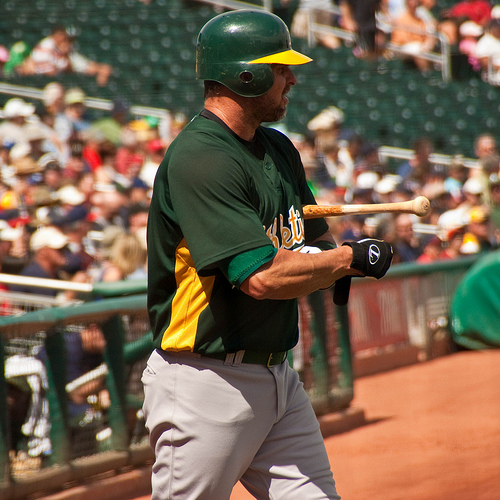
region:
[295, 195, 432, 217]
part of a brown bat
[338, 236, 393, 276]
a black and white glove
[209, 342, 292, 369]
a man's black belt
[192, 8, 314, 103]
a green and yellow helmet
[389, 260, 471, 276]
a long green pole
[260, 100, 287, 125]
a man's beard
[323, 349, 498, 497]
part of a tennis court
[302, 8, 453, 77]
a long gray rail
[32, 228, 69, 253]
a white baseball cap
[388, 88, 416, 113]
a green stadium seat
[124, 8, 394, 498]
Man wearing a green jersey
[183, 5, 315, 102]
Helmet on man's head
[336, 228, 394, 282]
Black glove on man's hand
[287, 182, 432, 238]
Bat under man's arm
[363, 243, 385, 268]
White logo on black glove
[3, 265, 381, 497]
Fence with green padding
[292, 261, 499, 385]
Sign posted on fence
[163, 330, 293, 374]
Back belt around man's waist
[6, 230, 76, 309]
Man wearing a white hat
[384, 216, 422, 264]
Man wearing a blue shirt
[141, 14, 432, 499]
a batter of a baseball game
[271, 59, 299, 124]
the face of a man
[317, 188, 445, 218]
the end of a baseball bat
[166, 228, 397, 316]
the arm of a baseball player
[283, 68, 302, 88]
the nose of a man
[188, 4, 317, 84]
the green and yellow helmet of a baseball batter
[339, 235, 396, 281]
a black and white glove on a hand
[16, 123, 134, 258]
the fans in the stadium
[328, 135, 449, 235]
the fans in the stadium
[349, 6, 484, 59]
the fans in the stadium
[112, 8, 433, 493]
Baseball player in the forefront.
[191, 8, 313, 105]
Green and yellow helmet.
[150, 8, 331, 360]
Green and yellow shirt on player.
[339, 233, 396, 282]
Black glove on the hand.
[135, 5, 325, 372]
Green belt on the man.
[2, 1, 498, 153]
Green stadium seating.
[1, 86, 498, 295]
crowd in the bleachers.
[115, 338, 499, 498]
Clay colored dirt on the ground.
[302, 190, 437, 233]
Wooden baseball bat.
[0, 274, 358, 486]
Green fencing in the background.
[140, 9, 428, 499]
the man dressed to play baseball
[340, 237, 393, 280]
the glove on the man's hand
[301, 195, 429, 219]
the bat the man is holding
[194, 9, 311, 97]
the helmet on the man's head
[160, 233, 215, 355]
the yellow part on the man's shirt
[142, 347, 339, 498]
the baseball pants on the man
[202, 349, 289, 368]
the belt on the man's pants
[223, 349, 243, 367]
the belt loops on the man's pants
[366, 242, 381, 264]
the design on the man's glove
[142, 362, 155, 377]
the pocket on the back of the man's pants